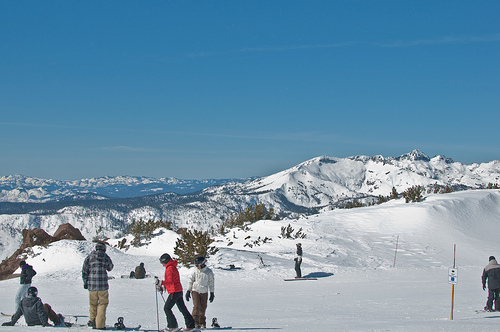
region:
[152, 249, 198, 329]
skier is next to skier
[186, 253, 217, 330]
skier is next to skier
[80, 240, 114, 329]
skier is next to skier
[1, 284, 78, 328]
skier is next to skier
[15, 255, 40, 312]
skier is next to skier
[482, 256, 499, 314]
skier is next to skier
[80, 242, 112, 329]
man wearing tan pants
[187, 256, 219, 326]
woman wearing brown pants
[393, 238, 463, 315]
pole markers stuck in the snow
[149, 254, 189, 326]
woman holding ski poles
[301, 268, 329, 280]
shadow of the skier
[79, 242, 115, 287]
blue and black plaid jacket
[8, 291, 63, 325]
person sitting in the snow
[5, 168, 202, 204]
mountains in the far distance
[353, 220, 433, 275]
tracks in the snow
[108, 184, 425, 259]
trees growing along the mountain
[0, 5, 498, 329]
a scene outside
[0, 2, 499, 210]
a blue sky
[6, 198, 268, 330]
some skiers on slope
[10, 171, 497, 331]
white snow on the ground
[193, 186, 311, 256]
green shrubs on the mountain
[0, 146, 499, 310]
a row of mountains on the background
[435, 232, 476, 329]
a sign in the ground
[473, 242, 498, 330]
a skier in gray and white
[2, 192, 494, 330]
group of people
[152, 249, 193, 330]
woman in a puffy red coat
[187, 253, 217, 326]
person in puffy white coat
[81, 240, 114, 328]
man wearing a plaid jacket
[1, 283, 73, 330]
person sitting in the snow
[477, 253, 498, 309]
man in light and dark gray coat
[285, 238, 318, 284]
person standing on skis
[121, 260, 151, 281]
person sitting with a snowboard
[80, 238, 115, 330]
man wearing khaki pants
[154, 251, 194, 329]
woman wearing black pants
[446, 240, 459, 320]
sign attached to a pole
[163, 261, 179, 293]
The red jacket the person is wearing.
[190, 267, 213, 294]
The white jacket the person is wearing.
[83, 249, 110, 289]
The plaid jacket the person is wearing.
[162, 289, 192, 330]
The black pants the person in the red is wearing.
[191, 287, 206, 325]
The dark brown pants the person in the white jacket is wearing.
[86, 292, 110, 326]
The beige pants the person in plaid is wearing.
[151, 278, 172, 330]
The ski poles of the person in red.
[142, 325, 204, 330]
The skis the person in red is standing on.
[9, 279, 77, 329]
The person in the gray jacket sitting down.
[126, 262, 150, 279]
The person in the distance sitting down.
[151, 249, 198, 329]
skier wearing red coat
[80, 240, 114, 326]
man wearing plaid jacket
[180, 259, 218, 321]
woman wearing white coat